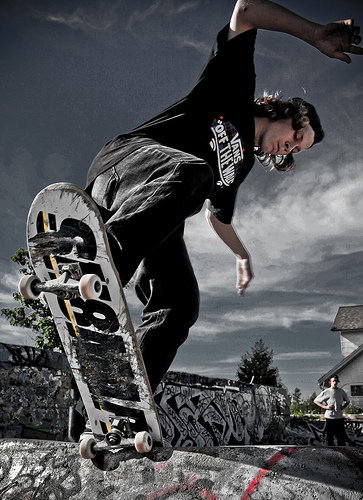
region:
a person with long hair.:
[240, 84, 349, 178]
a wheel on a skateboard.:
[71, 248, 108, 305]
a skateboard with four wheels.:
[17, 167, 187, 470]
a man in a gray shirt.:
[309, 362, 356, 421]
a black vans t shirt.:
[137, 27, 278, 256]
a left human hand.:
[228, 245, 262, 299]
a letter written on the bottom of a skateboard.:
[49, 281, 122, 335]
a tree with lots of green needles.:
[226, 338, 287, 405]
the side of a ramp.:
[2, 436, 345, 498]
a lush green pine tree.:
[228, 325, 304, 399]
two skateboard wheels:
[77, 432, 158, 460]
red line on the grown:
[230, 433, 311, 496]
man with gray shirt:
[311, 369, 355, 445]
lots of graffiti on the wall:
[176, 384, 256, 443]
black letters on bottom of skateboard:
[21, 171, 176, 469]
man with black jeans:
[85, 132, 202, 389]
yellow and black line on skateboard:
[34, 207, 90, 344]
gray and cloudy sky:
[263, 181, 340, 264]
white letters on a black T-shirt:
[199, 103, 247, 205]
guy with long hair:
[249, 80, 326, 187]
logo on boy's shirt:
[205, 112, 253, 196]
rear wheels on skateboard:
[77, 431, 158, 461]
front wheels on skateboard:
[17, 269, 105, 309]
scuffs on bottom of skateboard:
[67, 317, 147, 419]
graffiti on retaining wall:
[152, 381, 284, 442]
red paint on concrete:
[215, 446, 311, 498]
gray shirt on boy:
[313, 387, 348, 418]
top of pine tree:
[230, 335, 283, 387]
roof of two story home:
[330, 300, 361, 336]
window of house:
[348, 382, 361, 399]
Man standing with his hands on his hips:
[312, 374, 350, 447]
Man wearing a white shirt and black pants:
[312, 373, 351, 445]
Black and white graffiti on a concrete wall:
[0, 341, 361, 448]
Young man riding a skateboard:
[25, 1, 362, 460]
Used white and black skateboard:
[17, 181, 164, 458]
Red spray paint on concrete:
[221, 446, 300, 499]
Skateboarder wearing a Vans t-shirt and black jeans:
[16, 0, 357, 458]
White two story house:
[317, 304, 360, 411]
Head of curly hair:
[254, 87, 324, 169]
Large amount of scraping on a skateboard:
[49, 310, 154, 410]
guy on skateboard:
[1, 2, 361, 498]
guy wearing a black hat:
[4, 1, 342, 483]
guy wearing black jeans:
[9, 2, 356, 485]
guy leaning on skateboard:
[1, 0, 359, 485]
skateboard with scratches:
[12, 183, 169, 476]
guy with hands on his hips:
[311, 373, 362, 460]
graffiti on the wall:
[195, 372, 297, 442]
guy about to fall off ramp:
[3, 1, 360, 469]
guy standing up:
[309, 370, 360, 447]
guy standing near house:
[305, 300, 362, 443]